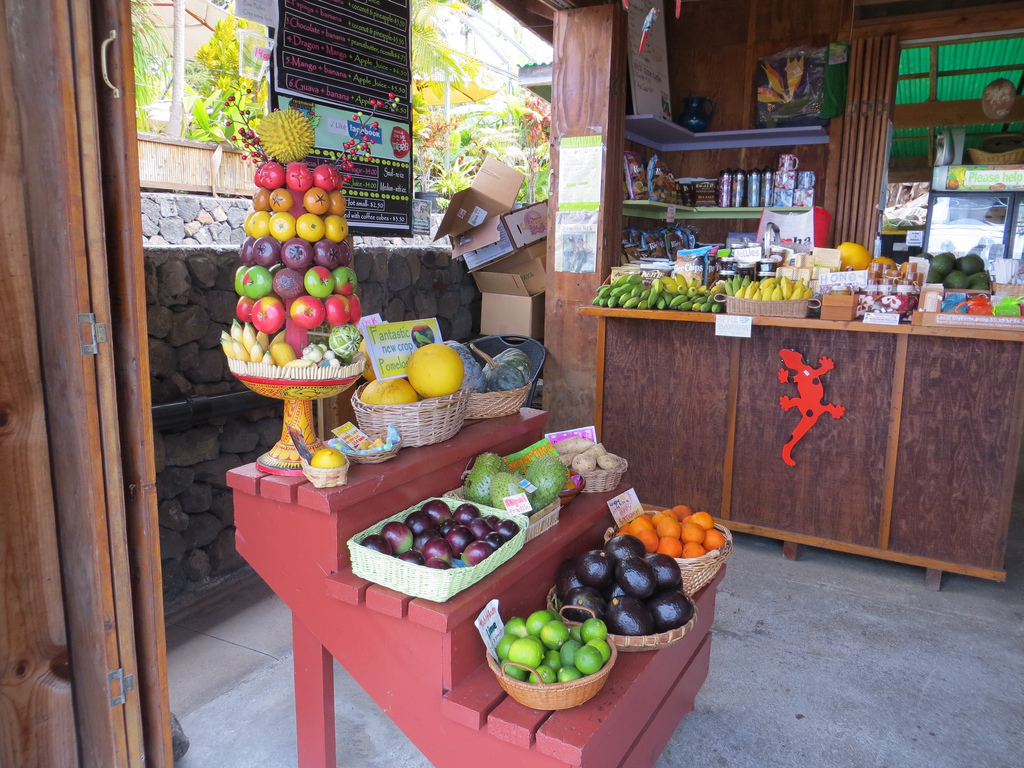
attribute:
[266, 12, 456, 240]
prices — product, for customers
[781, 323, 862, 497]
lizard — red, decorative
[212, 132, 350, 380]
fruits — stacked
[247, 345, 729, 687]
fruit — displayed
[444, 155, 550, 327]
boxes — piled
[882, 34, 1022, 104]
shed — green 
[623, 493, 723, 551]
oranges — displayed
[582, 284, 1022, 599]
counter — brown , wood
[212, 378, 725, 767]
rack — red 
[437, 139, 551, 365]
boxes — piled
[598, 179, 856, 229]
shelf — top